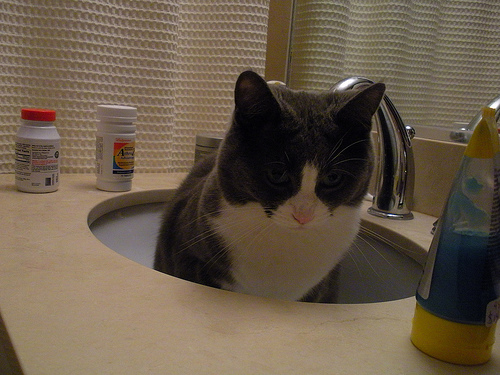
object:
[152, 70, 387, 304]
cat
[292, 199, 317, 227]
nose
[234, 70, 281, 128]
ear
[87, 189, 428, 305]
sink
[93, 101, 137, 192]
bottle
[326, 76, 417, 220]
faucet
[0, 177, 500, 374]
counter top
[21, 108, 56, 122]
cap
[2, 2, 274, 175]
curtain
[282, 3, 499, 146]
mirror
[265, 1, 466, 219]
wall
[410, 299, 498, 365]
lid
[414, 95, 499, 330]
tube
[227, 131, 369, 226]
face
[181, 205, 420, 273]
whisker